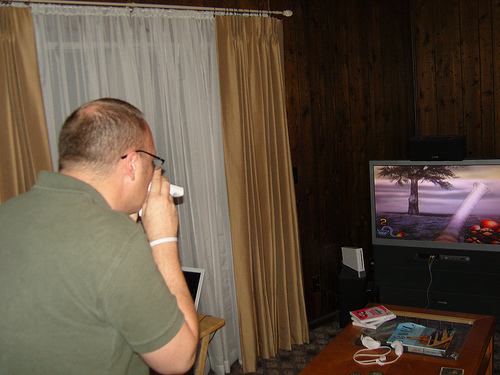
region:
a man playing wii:
[8, 95, 210, 373]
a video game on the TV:
[362, 151, 495, 256]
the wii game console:
[335, 239, 372, 285]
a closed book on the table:
[381, 315, 461, 365]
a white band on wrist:
[144, 220, 184, 255]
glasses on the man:
[115, 141, 170, 174]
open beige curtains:
[217, 15, 313, 368]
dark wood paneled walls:
[297, 2, 494, 158]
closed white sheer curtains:
[30, 3, 242, 369]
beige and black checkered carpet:
[233, 317, 345, 372]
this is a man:
[0, 104, 206, 364]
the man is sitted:
[0, 119, 212, 371]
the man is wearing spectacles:
[146, 158, 164, 168]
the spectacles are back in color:
[152, 149, 162, 161]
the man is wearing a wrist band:
[150, 237, 177, 247]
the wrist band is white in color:
[150, 229, 178, 251]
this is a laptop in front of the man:
[188, 268, 201, 285]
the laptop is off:
[189, 275, 201, 294]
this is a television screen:
[367, 166, 496, 243]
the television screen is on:
[370, 164, 495, 242]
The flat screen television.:
[369, 155, 498, 265]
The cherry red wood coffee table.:
[320, 342, 345, 374]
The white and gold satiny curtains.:
[2, 1, 291, 98]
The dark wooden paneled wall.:
[301, 1, 498, 114]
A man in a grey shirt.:
[1, 96, 197, 372]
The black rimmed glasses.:
[117, 147, 166, 169]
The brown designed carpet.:
[264, 352, 299, 374]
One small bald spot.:
[78, 101, 105, 122]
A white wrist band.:
[147, 235, 185, 245]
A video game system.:
[336, 240, 376, 284]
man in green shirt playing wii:
[19, 112, 274, 327]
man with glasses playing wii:
[34, 102, 198, 265]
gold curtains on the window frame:
[224, 78, 301, 292]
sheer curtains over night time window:
[153, 66, 233, 167]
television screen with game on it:
[337, 131, 487, 272]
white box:
[311, 235, 383, 295]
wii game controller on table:
[341, 329, 411, 366]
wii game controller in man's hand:
[132, 165, 189, 236]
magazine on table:
[386, 307, 471, 358]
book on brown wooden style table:
[308, 306, 375, 367]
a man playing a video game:
[31, 83, 496, 312]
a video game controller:
[349, 328, 427, 373]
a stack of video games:
[343, 296, 400, 331]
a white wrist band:
[139, 228, 199, 253]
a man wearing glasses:
[16, 76, 177, 228]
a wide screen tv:
[325, 119, 496, 288]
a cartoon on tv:
[351, 146, 498, 245]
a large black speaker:
[389, 122, 484, 168]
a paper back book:
[384, 308, 477, 372]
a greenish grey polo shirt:
[3, 154, 214, 374]